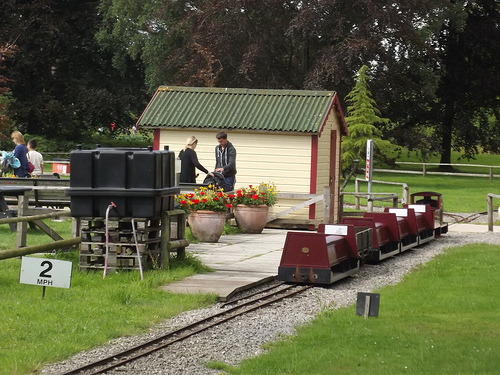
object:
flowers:
[179, 179, 234, 214]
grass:
[206, 240, 500, 373]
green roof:
[134, 82, 337, 133]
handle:
[361, 292, 370, 321]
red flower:
[245, 182, 257, 190]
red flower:
[234, 188, 247, 198]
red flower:
[212, 190, 224, 199]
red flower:
[191, 197, 201, 205]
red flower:
[250, 190, 261, 200]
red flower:
[198, 187, 207, 198]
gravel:
[35, 232, 500, 374]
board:
[17, 255, 75, 290]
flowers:
[228, 180, 279, 208]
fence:
[339, 156, 500, 213]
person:
[4, 128, 32, 180]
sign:
[17, 251, 74, 290]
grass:
[226, 215, 259, 336]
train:
[277, 191, 449, 285]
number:
[37, 258, 53, 281]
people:
[213, 129, 238, 192]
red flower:
[177, 198, 195, 207]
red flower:
[199, 185, 203, 198]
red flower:
[233, 193, 246, 203]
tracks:
[191, 322, 216, 334]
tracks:
[189, 313, 205, 328]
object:
[354, 290, 382, 318]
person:
[174, 132, 215, 187]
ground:
[0, 171, 499, 374]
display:
[35, 260, 53, 288]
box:
[68, 149, 102, 218]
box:
[94, 148, 130, 219]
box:
[123, 151, 176, 220]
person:
[26, 135, 46, 177]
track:
[60, 283, 318, 373]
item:
[185, 208, 226, 245]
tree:
[169, 0, 389, 92]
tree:
[85, 0, 197, 97]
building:
[133, 85, 349, 223]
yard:
[339, 140, 500, 223]